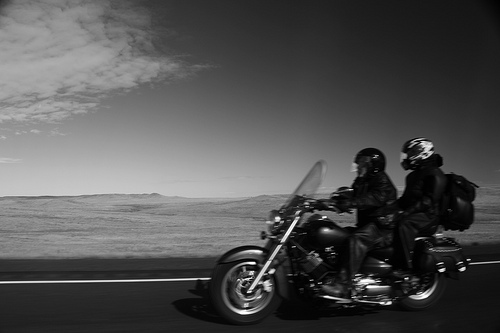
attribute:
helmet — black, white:
[351, 142, 389, 178]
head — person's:
[350, 143, 391, 178]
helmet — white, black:
[399, 133, 434, 170]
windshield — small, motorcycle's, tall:
[276, 159, 328, 217]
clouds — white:
[6, 1, 207, 142]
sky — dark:
[6, 14, 499, 194]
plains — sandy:
[1, 183, 500, 260]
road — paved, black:
[3, 248, 499, 330]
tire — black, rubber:
[211, 260, 287, 322]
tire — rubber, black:
[396, 275, 446, 309]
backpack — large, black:
[437, 172, 485, 228]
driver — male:
[332, 143, 400, 300]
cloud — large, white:
[4, 8, 201, 147]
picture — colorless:
[4, 3, 499, 321]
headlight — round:
[263, 208, 282, 237]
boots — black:
[318, 281, 349, 293]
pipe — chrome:
[314, 290, 400, 312]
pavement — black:
[3, 248, 499, 327]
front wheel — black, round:
[209, 257, 283, 320]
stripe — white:
[2, 255, 496, 291]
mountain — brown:
[6, 191, 499, 256]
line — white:
[0, 256, 500, 287]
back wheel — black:
[400, 273, 451, 309]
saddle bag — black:
[413, 237, 475, 273]